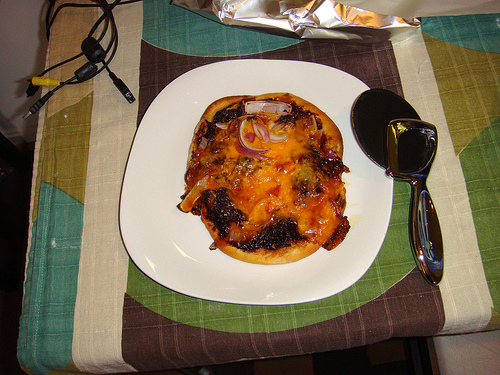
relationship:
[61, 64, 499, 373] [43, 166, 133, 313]
tablecloth has design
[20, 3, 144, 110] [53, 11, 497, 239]
cables on table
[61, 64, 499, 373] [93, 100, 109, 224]
tablecloth has white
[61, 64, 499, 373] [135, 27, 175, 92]
tablecloth has brown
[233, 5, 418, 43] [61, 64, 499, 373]
foil on tablecloth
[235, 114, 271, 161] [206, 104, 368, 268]
onion on pizza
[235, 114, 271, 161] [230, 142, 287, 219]
onion covered in cheese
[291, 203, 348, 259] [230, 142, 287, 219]
crust has cheese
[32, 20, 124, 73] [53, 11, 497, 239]
cords on table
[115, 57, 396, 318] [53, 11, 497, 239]
plate on table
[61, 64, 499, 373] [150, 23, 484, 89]
tablecloth has stripes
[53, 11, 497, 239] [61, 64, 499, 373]
table covered in tablecloth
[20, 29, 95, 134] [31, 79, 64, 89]
yellow tip on cord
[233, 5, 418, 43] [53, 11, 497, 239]
foil on table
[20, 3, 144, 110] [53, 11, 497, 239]
wires on table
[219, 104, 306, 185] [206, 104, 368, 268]
onions on top of pizza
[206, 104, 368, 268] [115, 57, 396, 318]
food on plate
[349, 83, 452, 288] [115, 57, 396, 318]
utensil next to plate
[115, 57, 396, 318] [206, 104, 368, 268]
plate with pizza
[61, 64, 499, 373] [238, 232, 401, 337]
tablecloth has green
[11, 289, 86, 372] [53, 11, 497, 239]
corner of table